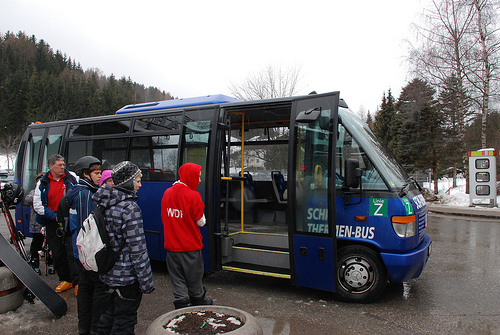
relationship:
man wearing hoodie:
[158, 162, 215, 308] [158, 157, 207, 252]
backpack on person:
[73, 195, 128, 280] [74, 155, 156, 334]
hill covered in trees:
[4, 34, 180, 154] [406, 1, 498, 218]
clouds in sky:
[5, 0, 97, 68] [3, 0, 496, 127]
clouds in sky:
[48, 25, 97, 58] [61, 0, 306, 95]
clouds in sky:
[283, 13, 388, 63] [12, 2, 484, 92]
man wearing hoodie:
[160, 161, 214, 310] [160, 161, 207, 252]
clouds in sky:
[168, 4, 360, 109] [3, 0, 496, 127]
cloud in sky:
[90, 39, 172, 87] [69, 2, 405, 55]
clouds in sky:
[316, 41, 396, 102] [286, 12, 393, 54]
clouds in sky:
[239, 17, 290, 66] [93, 0, 332, 74]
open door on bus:
[176, 90, 338, 292] [11, 90, 433, 302]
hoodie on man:
[159, 159, 204, 250] [162, 158, 219, 288]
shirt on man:
[35, 170, 80, 217] [31, 150, 81, 272]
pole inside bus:
[239, 117, 247, 232] [11, 90, 433, 302]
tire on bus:
[333, 248, 383, 301] [11, 90, 433, 302]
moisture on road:
[428, 215, 498, 334] [0, 185, 500, 334]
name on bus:
[303, 204, 330, 223] [11, 90, 433, 302]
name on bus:
[303, 220, 377, 239] [11, 90, 433, 302]